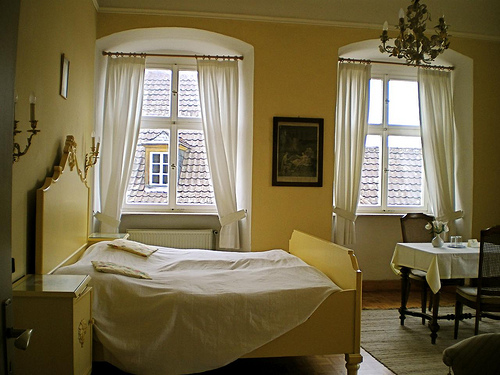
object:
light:
[83, 132, 103, 178]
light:
[377, 1, 452, 69]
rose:
[424, 221, 434, 231]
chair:
[399, 212, 462, 340]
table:
[395, 237, 500, 348]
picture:
[269, 116, 326, 188]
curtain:
[332, 55, 372, 254]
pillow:
[92, 259, 152, 280]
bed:
[32, 132, 364, 375]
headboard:
[34, 132, 90, 276]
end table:
[5, 273, 95, 375]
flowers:
[423, 217, 450, 235]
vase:
[431, 230, 444, 248]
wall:
[98, 9, 499, 289]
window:
[347, 65, 453, 210]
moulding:
[337, 36, 474, 70]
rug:
[356, 306, 498, 374]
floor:
[93, 289, 499, 373]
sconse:
[9, 91, 41, 170]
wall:
[10, 0, 99, 373]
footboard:
[288, 227, 365, 374]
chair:
[453, 222, 498, 340]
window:
[106, 61, 237, 210]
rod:
[98, 47, 247, 61]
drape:
[98, 50, 147, 234]